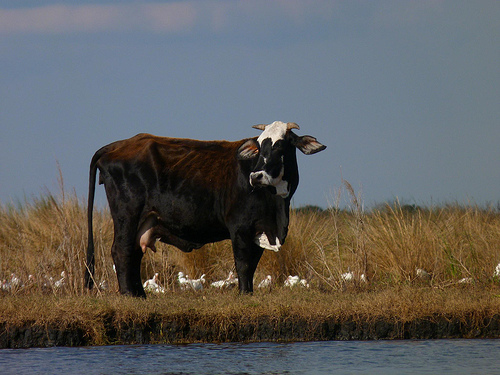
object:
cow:
[83, 122, 326, 301]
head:
[239, 121, 326, 186]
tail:
[83, 145, 99, 294]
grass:
[0, 199, 499, 343]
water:
[6, 343, 498, 374]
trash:
[260, 275, 311, 294]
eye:
[274, 142, 289, 152]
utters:
[132, 222, 159, 260]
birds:
[143, 271, 165, 297]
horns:
[248, 117, 301, 132]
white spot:
[257, 126, 293, 143]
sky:
[1, 6, 497, 204]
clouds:
[0, 6, 270, 37]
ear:
[233, 137, 261, 160]